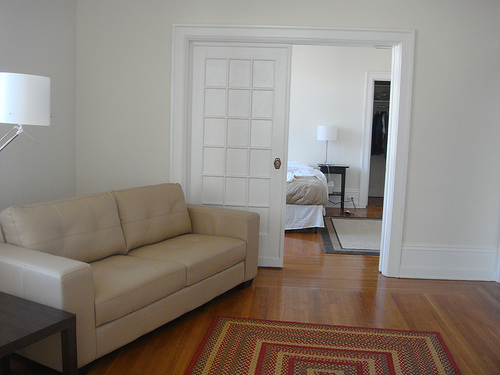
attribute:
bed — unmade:
[285, 160, 335, 235]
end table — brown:
[2, 294, 79, 368]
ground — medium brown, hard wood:
[419, 132, 437, 153]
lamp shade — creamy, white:
[1, 67, 53, 137]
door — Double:
[196, 51, 293, 278]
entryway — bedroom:
[163, 15, 409, 284]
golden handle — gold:
[267, 152, 284, 176]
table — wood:
[6, 279, 91, 370]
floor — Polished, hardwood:
[208, 271, 429, 372]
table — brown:
[0, 291, 79, 373]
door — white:
[187, 38, 291, 270]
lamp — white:
[0, 70, 52, 128]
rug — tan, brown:
[324, 215, 384, 262]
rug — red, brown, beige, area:
[177, 311, 471, 373]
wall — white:
[3, 2, 498, 279]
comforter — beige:
[286, 178, 322, 204]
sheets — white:
[290, 205, 327, 234]